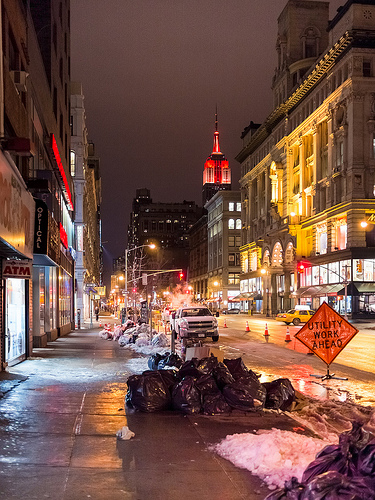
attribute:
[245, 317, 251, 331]
cone — white , Orange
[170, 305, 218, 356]
truck — white 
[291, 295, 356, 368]
sign — orange 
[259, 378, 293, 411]
trashbag — black 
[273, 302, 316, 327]
cab — yellow 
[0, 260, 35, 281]
sign — small , white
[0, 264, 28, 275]
letters — red 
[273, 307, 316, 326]
cab — yellow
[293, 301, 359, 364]
sign — white 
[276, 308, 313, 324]
taxi — yellow 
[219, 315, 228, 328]
cone — four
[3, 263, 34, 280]
sign — red and white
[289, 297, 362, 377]
sign — orange, black 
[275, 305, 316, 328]
taxi — yellow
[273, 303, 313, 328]
taxi cab — yellow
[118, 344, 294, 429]
trash bags — black 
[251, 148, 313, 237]
lighting — red